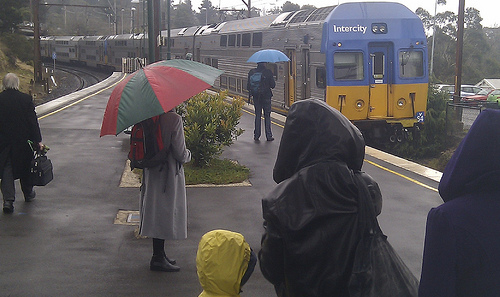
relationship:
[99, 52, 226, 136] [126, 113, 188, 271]
woman holds umbrella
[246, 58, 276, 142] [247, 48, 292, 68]
man holding umbrella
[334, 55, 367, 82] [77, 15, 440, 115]
window front train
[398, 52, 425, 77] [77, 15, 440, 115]
window front train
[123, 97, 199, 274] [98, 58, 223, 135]
woman holding umbrella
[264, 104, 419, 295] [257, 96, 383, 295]
person wearing raincoat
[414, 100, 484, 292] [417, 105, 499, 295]
person wearing cloak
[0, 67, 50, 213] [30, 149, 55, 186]
man carrying briefcase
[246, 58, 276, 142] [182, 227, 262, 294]
man wears hood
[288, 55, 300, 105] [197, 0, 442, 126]
door of train